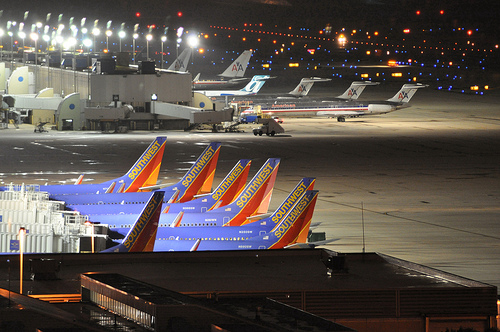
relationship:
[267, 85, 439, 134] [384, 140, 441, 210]
airplane on runway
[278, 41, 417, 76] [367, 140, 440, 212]
lights at airport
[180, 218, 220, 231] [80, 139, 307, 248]
windows on airplane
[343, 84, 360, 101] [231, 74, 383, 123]
logo on tail of plane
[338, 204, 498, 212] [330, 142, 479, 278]
line on roadway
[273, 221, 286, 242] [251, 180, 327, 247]
letter on tail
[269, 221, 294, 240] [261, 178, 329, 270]
letter on tail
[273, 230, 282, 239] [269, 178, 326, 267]
letter on tail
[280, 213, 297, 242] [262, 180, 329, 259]
letter on tail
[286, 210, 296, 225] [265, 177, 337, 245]
letter on tail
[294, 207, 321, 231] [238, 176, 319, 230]
letter on plane tail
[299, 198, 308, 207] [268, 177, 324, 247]
letter on plane tail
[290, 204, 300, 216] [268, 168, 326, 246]
letter on plane tail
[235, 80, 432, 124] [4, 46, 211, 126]
airplane at gate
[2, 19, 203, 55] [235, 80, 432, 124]
lights for airplane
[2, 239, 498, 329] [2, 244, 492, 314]
building has roof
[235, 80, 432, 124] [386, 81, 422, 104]
airplane has tail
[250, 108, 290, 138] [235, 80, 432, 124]
plane by airplane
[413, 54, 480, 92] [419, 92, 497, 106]
lights by runway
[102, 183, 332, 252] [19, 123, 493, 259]
airplane on runway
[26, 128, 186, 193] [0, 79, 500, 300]
airplane on roadway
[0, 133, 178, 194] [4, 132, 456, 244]
airplane on runway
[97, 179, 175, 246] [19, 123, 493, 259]
airplane on runway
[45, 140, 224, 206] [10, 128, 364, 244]
airplane on runway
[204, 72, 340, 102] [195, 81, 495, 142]
airplane on runway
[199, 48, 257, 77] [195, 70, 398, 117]
airplane on runway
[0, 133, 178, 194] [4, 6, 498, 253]
airplane in airport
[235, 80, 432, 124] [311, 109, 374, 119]
airplane has wing